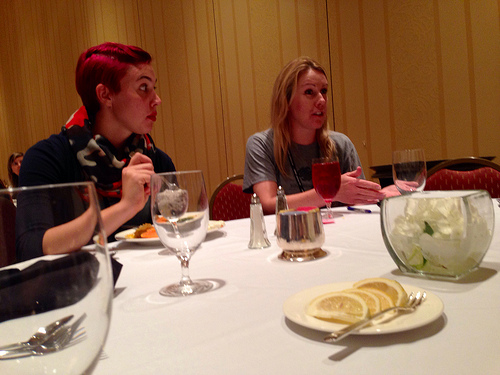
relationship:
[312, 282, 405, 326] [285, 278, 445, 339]
lemon slices are on plate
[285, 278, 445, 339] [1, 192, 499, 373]
plate on table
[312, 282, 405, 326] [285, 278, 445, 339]
lemon slices on plate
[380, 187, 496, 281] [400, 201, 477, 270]
bowl holding flowers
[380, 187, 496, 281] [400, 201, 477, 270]
container with sugar packs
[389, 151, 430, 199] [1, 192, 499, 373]
glass on table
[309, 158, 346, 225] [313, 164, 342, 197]
glass with liquid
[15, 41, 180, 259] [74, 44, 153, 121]
woman has red hair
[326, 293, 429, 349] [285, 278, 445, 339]
forks are on plate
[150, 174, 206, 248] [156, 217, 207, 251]
glass filled with water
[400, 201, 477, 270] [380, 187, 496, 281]
flowers in vase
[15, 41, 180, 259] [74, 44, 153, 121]
woman has hair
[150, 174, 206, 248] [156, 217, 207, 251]
glass with water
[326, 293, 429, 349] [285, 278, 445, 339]
forks on plate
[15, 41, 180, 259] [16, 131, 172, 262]
woman has hoodie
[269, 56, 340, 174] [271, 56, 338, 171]
girl has hair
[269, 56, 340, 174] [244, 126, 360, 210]
girl has shirt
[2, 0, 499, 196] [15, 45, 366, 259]
wall behind women